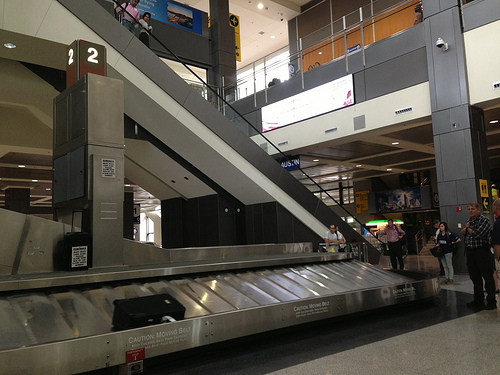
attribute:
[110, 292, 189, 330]
suitcase — black